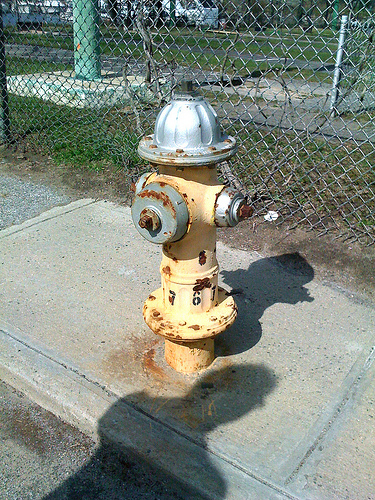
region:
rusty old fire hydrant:
[120, 74, 258, 376]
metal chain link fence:
[3, 0, 374, 252]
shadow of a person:
[35, 356, 283, 497]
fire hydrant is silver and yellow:
[119, 75, 258, 378]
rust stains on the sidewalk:
[94, 336, 247, 400]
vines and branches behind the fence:
[116, 1, 354, 226]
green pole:
[59, 1, 107, 81]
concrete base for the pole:
[4, 44, 178, 116]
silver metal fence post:
[326, 9, 351, 123]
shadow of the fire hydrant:
[200, 245, 321, 373]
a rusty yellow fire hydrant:
[125, 73, 263, 376]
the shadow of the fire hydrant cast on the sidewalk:
[208, 240, 337, 364]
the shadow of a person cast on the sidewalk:
[36, 355, 291, 498]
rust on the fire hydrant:
[191, 249, 217, 296]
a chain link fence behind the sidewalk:
[0, 0, 373, 249]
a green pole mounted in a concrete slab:
[0, 1, 166, 116]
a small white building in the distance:
[147, 0, 226, 30]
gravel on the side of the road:
[1, 385, 142, 498]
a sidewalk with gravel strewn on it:
[0, 178, 374, 498]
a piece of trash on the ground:
[264, 206, 281, 223]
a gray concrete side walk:
[12, 192, 96, 359]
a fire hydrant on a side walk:
[131, 88, 264, 387]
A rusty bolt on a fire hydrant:
[136, 201, 162, 241]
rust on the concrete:
[91, 351, 172, 399]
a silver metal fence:
[95, 32, 275, 93]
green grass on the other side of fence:
[65, 112, 138, 160]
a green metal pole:
[54, 5, 111, 71]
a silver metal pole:
[318, 12, 356, 120]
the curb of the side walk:
[15, 399, 226, 482]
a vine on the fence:
[140, 5, 177, 91]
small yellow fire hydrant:
[115, 87, 267, 379]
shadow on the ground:
[29, 356, 289, 497]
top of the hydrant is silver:
[129, 94, 244, 169]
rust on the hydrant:
[159, 265, 174, 278]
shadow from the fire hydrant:
[209, 245, 319, 355]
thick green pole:
[65, 0, 107, 79]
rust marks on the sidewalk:
[139, 347, 163, 383]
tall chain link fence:
[2, 1, 374, 262]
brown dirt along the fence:
[230, 217, 374, 292]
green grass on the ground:
[2, 51, 373, 234]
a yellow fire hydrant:
[130, 90, 250, 369]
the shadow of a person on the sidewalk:
[96, 362, 279, 498]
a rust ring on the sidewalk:
[142, 338, 236, 382]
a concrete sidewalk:
[0, 198, 373, 499]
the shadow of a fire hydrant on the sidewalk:
[207, 242, 319, 365]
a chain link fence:
[1, 0, 372, 243]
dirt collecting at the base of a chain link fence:
[0, 146, 373, 298]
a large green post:
[71, 0, 103, 78]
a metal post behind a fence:
[328, 12, 352, 117]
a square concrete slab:
[4, 65, 168, 110]